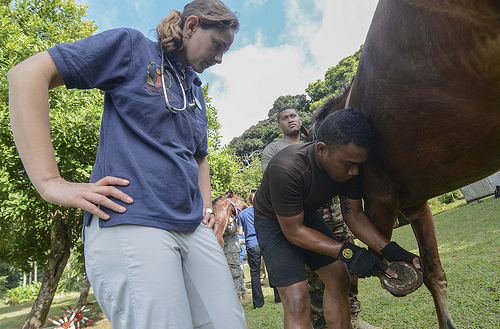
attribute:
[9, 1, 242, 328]
woman — wearing watch, wearing blue shirt, wearing pants, placing hand on hip, doctor, looking down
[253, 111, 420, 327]
man — inspecting, holding horse hoof, pointing, lifting, bent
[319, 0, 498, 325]
horse — brown, big, standing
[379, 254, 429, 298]
horse hoof — being inspected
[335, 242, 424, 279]
hands of man — gloved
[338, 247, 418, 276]
gloves — black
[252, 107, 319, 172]
2nd man — wearing t-shirt, looking ahead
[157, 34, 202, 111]
stethoscope — around neck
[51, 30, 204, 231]
t-shirt — blue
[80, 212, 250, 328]
pants — light blue, light grey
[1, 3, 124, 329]
tree — behind woman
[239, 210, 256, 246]
back — not facing camera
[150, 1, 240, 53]
hair — brown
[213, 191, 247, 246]
horse — wearing bridle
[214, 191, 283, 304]
horse and trainer — in background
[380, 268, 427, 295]
horse shoe — in man's hand, silver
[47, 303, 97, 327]
spiky objects — orange, round, white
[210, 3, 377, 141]
clouds — thick, white